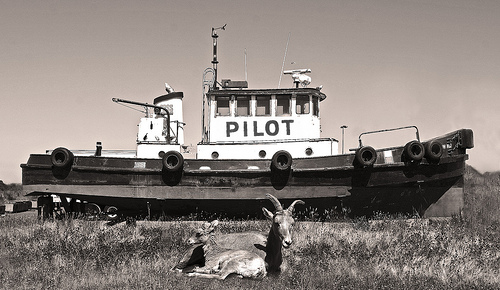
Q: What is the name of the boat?
A: Pilot.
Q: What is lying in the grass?
A: Antelopes.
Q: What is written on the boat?
A: PILOT.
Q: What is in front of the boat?
A: Goats.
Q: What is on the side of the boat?
A: Tires.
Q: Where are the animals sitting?
A: Grass.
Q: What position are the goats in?
A: Sitting.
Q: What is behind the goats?
A: Boat.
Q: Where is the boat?
A: Land.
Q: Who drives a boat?
A: Captain.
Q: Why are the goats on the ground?
A: Resting.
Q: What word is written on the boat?
A: "Pilot.".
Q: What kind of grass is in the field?
A: Dry grass.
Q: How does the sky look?
A: Dark grey.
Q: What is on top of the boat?
A: Rigging.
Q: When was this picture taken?
A: During the day.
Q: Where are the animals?
A: In front of the boat.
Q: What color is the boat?
A: Black and white.